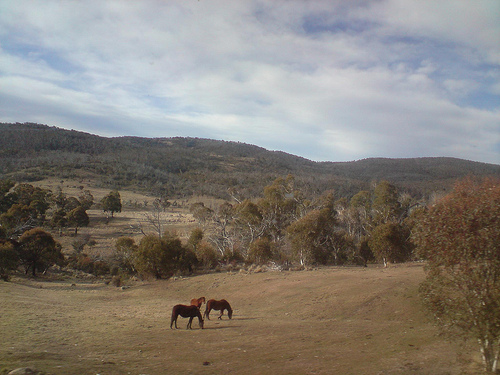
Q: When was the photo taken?
A: Daytime.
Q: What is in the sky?
A: Clouds.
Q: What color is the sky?
A: Blue.